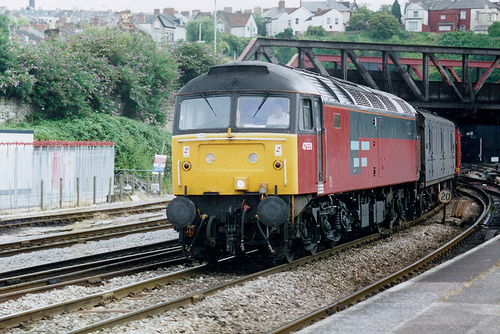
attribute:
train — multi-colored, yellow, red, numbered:
[155, 58, 480, 259]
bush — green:
[35, 117, 154, 140]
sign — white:
[437, 189, 456, 224]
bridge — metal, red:
[337, 41, 499, 108]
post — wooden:
[38, 177, 49, 213]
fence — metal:
[1, 169, 170, 217]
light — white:
[231, 176, 252, 194]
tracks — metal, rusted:
[37, 241, 184, 319]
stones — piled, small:
[220, 288, 286, 328]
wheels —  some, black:
[284, 199, 361, 255]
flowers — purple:
[82, 54, 121, 100]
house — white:
[263, 8, 345, 35]